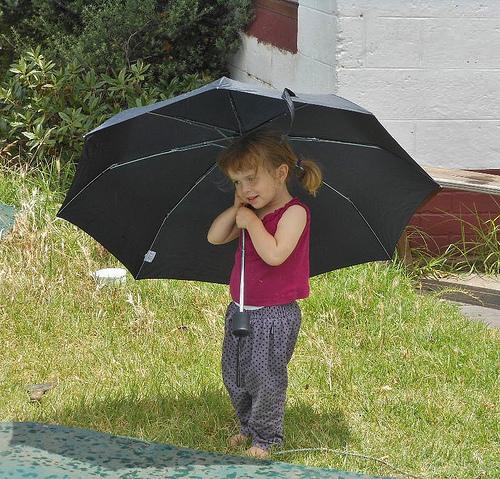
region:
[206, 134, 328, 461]
a young girl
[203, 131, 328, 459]
a young girl in the grass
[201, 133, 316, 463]
the girl is barefoot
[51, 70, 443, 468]
a child holding an umbrella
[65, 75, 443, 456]
a young girl holds an umbrella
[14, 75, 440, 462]
the girl holds an open umbrella on a sunny day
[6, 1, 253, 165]
bushes next to the building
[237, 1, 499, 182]
a white brick building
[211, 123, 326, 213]
the girl's hair is in pigtails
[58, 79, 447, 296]
the umbrella is black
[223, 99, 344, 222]
the head of a girl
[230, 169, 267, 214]
the eyes of a girl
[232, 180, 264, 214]
the nose of a girl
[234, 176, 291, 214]
the mouth of a girl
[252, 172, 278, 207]
the cheek of a girl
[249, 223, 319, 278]
the elbow of a girl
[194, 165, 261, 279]
the arm of a girl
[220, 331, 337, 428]
the legs of a girl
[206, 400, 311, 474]
the feet of a girl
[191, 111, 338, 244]
the red hair of a girl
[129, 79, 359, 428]
A little girl under an umbrella.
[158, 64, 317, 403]
The girl is holding the umbrella.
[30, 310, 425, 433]
The grass is green.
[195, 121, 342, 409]
The little girl is standing in the grass.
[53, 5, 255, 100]
Bushes by the house.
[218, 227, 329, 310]
The shirt is red.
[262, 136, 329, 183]
The girl hair is in a ponytail.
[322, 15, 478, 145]
The building is white.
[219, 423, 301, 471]
The girl is not wearing any shoes.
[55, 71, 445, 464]
Female toddler holding an umbrella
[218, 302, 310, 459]
The little girl is wearing gray pants with black polka dots.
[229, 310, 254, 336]
The umbrella has a large black knob on the end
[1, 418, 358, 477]
A little rain spatters the paved surface next to the little girl.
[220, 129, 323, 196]
The girl's brown hair is tied in a short pony tail.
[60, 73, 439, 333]
A large black umbrella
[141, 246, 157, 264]
White manufacturer's tag on the inside of the umbrella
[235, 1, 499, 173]
A cement block wall painted white is behind the girl.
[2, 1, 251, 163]
Some leafy shrubs are next to the block wall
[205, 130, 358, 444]
this is a small girl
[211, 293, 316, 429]
the girl is in pants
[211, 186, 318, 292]
the girl is in a pink top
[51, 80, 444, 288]
this is an umbrella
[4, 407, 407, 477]
this is a picnic mat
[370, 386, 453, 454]
this is grass on the field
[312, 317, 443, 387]
this is grass on the field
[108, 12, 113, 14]
A green leaf on a plant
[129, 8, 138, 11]
A green leaf on a plant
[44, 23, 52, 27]
A green leaf on a plant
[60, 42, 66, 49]
A green leaf on a plant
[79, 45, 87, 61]
A green leaf on a plant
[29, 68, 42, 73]
A green leaf on a plant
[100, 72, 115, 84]
A green leaf on a plant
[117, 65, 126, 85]
A green leaf on a plant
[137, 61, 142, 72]
A green leaf on a plant